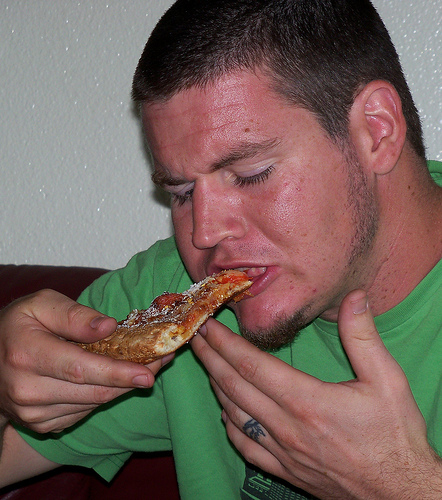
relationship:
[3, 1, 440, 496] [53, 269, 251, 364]
man eating pizza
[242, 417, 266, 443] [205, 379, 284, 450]
tattoo on finger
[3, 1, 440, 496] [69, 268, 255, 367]
man eating pizza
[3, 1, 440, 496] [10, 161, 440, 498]
man wearing green shirt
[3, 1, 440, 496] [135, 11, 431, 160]
man has hair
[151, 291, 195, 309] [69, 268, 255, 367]
pepperoni on pizza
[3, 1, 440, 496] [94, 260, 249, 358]
man eating pizza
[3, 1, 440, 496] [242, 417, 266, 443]
man has tattoo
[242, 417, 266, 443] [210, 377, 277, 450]
tattoo on finger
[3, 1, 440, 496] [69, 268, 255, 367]
man biting into pizza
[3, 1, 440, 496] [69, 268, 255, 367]
man consuming pizza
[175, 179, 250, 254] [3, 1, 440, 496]
nose on man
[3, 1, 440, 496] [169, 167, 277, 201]
man with eye lashes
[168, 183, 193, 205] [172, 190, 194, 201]
eye with eyelashes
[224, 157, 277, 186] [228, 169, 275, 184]
eye with eyelashes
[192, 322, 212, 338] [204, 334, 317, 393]
finger nail on finger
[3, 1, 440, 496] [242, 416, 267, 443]
man with a tattoo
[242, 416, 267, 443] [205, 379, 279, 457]
tattoo on h finger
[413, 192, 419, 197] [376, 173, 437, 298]
freckle on neck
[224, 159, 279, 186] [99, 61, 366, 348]
eye on man